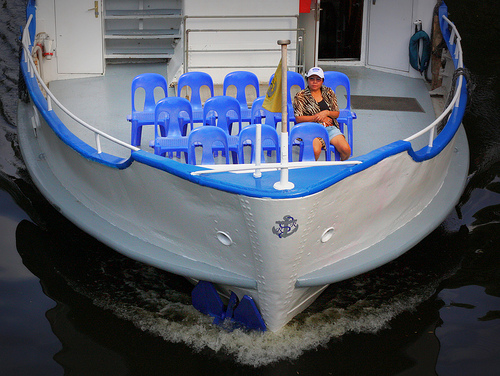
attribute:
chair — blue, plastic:
[126, 71, 171, 146]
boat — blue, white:
[20, 4, 470, 334]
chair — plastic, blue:
[232, 113, 297, 178]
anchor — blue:
[194, 283, 268, 335]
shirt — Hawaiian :
[289, 73, 352, 137]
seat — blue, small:
[155, 63, 236, 130]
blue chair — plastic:
[128, 73, 170, 149]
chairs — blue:
[128, 71, 352, 160]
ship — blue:
[14, 1, 476, 340]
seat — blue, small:
[152, 94, 199, 171]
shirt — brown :
[292, 85, 339, 115]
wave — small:
[82, 275, 439, 362]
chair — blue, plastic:
[239, 124, 281, 170]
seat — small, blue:
[130, 79, 174, 156]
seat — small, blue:
[112, 71, 175, 141]